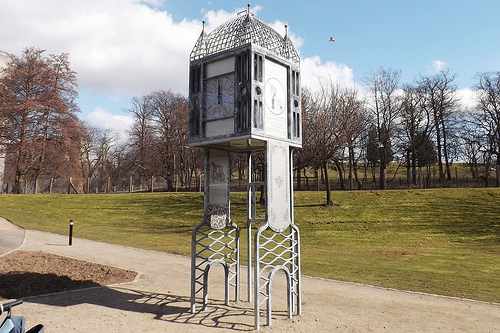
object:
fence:
[0, 163, 500, 194]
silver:
[266, 140, 291, 233]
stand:
[188, 3, 300, 330]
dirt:
[0, 252, 138, 301]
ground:
[0, 164, 499, 333]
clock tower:
[188, 3, 303, 329]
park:
[0, 0, 499, 333]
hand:
[217, 79, 221, 104]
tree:
[25, 52, 90, 194]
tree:
[318, 73, 378, 191]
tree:
[151, 88, 190, 192]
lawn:
[0, 187, 500, 302]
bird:
[328, 36, 335, 42]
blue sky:
[0, 0, 499, 165]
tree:
[120, 94, 159, 190]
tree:
[293, 73, 376, 206]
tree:
[366, 121, 394, 183]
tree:
[394, 97, 436, 186]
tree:
[461, 71, 499, 188]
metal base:
[191, 219, 302, 330]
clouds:
[0, 0, 499, 161]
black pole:
[69, 220, 74, 246]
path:
[0, 218, 499, 333]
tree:
[0, 46, 51, 195]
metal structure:
[186, 1, 304, 331]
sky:
[0, 0, 499, 167]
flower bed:
[0, 250, 144, 302]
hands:
[272, 95, 276, 109]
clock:
[201, 71, 234, 122]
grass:
[414, 199, 474, 226]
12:
[216, 79, 221, 84]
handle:
[234, 44, 265, 136]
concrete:
[0, 220, 499, 332]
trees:
[0, 46, 500, 194]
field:
[0, 162, 500, 304]